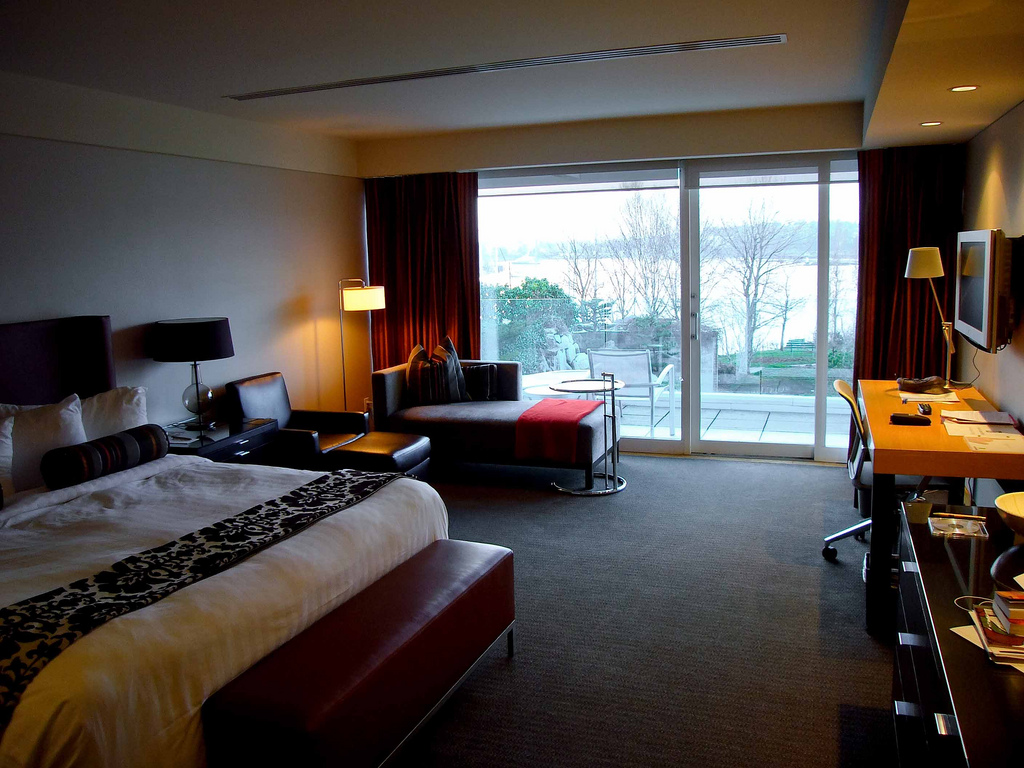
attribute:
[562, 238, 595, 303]
branch — tree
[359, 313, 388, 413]
pole — small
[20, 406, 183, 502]
pillow — bedroll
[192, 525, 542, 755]
bench — cushioned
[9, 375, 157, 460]
pillows — white